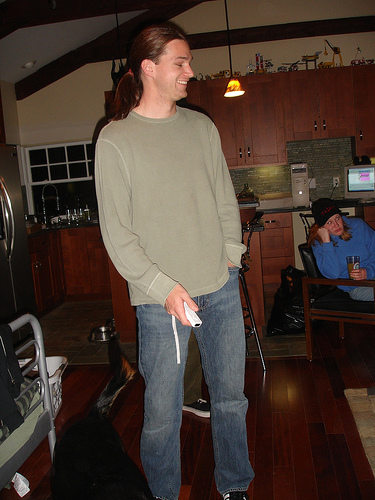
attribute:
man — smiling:
[93, 20, 256, 499]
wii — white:
[179, 300, 204, 330]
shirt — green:
[93, 107, 249, 309]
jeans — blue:
[136, 266, 257, 498]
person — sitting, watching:
[316, 197, 373, 303]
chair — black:
[302, 244, 375, 365]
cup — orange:
[346, 254, 362, 275]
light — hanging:
[222, 79, 247, 100]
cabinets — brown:
[197, 69, 374, 162]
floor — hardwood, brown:
[13, 354, 375, 500]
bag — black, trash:
[266, 263, 314, 337]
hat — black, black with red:
[311, 198, 343, 223]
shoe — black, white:
[179, 396, 213, 420]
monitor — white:
[341, 163, 374, 201]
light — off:
[19, 59, 38, 73]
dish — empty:
[89, 322, 113, 348]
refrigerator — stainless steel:
[2, 105, 37, 344]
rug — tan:
[247, 334, 310, 362]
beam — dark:
[189, 1, 375, 50]